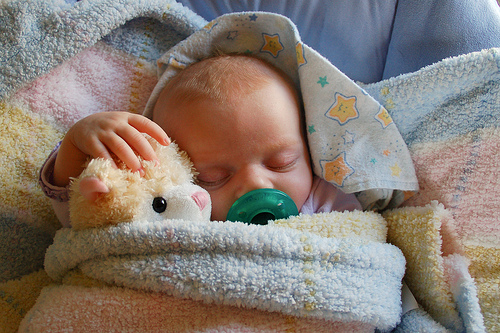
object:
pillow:
[179, 0, 499, 87]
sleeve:
[37, 143, 79, 230]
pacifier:
[226, 189, 299, 224]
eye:
[264, 152, 300, 173]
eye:
[194, 165, 233, 191]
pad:
[182, 0, 500, 83]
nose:
[232, 161, 275, 202]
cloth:
[136, 10, 420, 212]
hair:
[163, 42, 280, 107]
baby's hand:
[67, 110, 171, 178]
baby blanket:
[0, 0, 500, 333]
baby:
[20, 56, 407, 333]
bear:
[65, 133, 211, 227]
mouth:
[224, 189, 298, 226]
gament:
[37, 140, 363, 232]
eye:
[151, 196, 168, 214]